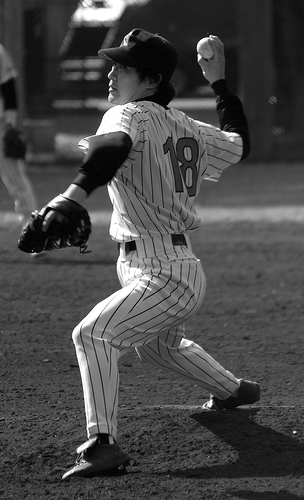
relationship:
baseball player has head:
[18, 28, 262, 480] [98, 27, 175, 104]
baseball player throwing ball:
[18, 28, 262, 480] [194, 34, 216, 60]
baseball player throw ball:
[18, 28, 262, 480] [195, 31, 217, 60]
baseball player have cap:
[18, 28, 262, 480] [99, 29, 171, 75]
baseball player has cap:
[18, 28, 262, 480] [99, 29, 171, 75]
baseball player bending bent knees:
[18, 28, 262, 480] [63, 300, 215, 385]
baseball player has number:
[18, 28, 262, 480] [157, 121, 209, 199]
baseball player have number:
[18, 28, 262, 480] [157, 121, 209, 199]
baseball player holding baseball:
[18, 28, 262, 480] [194, 34, 219, 58]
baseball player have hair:
[18, 28, 262, 480] [135, 65, 175, 105]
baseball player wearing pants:
[18, 28, 262, 480] [59, 232, 261, 478]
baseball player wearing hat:
[18, 28, 262, 480] [98, 23, 177, 74]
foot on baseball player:
[200, 376, 261, 413] [18, 28, 262, 480]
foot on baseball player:
[60, 436, 130, 485] [18, 28, 262, 480]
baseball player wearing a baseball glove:
[18, 28, 262, 480] [15, 191, 94, 263]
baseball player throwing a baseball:
[18, 28, 262, 480] [182, 29, 211, 62]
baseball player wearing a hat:
[18, 28, 262, 480] [96, 26, 177, 70]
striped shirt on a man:
[110, 143, 203, 264] [41, 28, 261, 478]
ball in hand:
[196, 36, 214, 60] [199, 28, 225, 94]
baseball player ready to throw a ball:
[18, 28, 262, 480] [174, 36, 224, 63]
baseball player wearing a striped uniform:
[18, 28, 262, 480] [72, 101, 243, 439]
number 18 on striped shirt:
[160, 135, 198, 195] [110, 143, 203, 264]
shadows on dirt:
[155, 408, 299, 499] [173, 400, 300, 482]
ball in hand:
[196, 36, 214, 60] [46, 199, 110, 246]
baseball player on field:
[16, 28, 258, 480] [225, 240, 286, 298]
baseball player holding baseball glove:
[18, 28, 262, 480] [18, 192, 94, 254]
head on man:
[96, 30, 178, 82] [83, 23, 267, 328]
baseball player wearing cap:
[18, 28, 262, 480] [76, 20, 183, 83]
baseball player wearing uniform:
[18, 28, 262, 480] [125, 109, 195, 312]